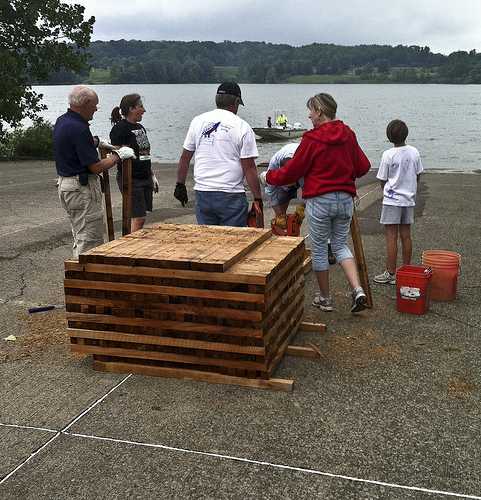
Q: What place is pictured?
A: It is a road.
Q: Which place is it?
A: It is a road.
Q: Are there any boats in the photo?
A: Yes, there is a boat.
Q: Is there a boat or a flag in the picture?
A: Yes, there is a boat.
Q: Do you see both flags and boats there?
A: No, there is a boat but no flags.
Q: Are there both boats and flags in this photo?
A: No, there is a boat but no flags.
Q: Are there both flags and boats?
A: No, there is a boat but no flags.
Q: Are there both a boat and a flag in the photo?
A: No, there is a boat but no flags.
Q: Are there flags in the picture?
A: No, there are no flags.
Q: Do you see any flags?
A: No, there are no flags.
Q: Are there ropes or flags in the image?
A: No, there are no flags or ropes.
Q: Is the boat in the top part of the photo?
A: Yes, the boat is in the top of the image.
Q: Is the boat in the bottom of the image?
A: No, the boat is in the top of the image.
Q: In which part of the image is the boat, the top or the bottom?
A: The boat is in the top of the image.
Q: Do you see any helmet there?
A: No, there are no helmets.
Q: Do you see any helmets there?
A: No, there are no helmets.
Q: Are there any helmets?
A: No, there are no helmets.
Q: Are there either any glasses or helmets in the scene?
A: No, there are no helmets or glasses.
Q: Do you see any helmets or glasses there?
A: No, there are no helmets or glasses.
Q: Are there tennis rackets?
A: No, there are no tennis rackets.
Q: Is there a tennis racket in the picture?
A: No, there are no rackets.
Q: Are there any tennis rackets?
A: No, there are no tennis rackets.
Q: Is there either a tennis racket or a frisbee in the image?
A: No, there are no rackets or frisbees.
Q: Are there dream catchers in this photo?
A: No, there are no dream catchers.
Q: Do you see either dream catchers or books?
A: No, there are no dream catchers or books.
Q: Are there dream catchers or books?
A: No, there are no dream catchers or books.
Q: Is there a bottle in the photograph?
A: No, there are no bottles.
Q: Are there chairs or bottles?
A: No, there are no bottles or chairs.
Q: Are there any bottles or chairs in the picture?
A: No, there are no bottles or chairs.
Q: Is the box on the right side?
A: Yes, the box is on the right of the image.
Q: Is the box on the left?
A: No, the box is on the right of the image.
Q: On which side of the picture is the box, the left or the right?
A: The box is on the right of the image.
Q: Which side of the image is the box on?
A: The box is on the right of the image.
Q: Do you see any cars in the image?
A: No, there are no cars.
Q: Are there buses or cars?
A: No, there are no cars or buses.